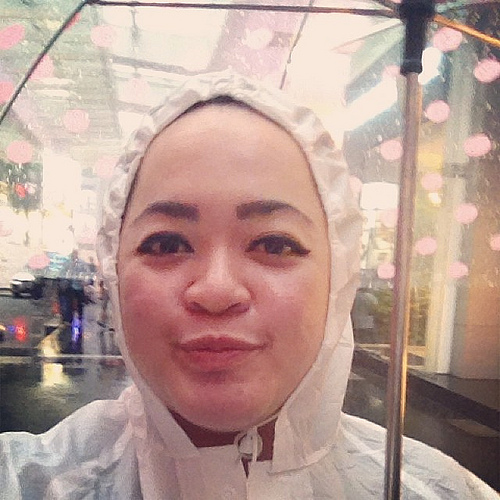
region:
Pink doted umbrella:
[359, 12, 493, 349]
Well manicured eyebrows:
[128, 185, 324, 241]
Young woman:
[58, 116, 353, 445]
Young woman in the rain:
[45, 111, 445, 445]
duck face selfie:
[142, 292, 320, 387]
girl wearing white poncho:
[25, 383, 492, 498]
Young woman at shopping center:
[75, 11, 495, 427]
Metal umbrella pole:
[377, 42, 417, 497]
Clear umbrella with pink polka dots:
[0, 0, 490, 82]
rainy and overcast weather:
[13, 13, 497, 158]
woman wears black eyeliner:
[131, 229, 312, 269]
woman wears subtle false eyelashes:
[126, 236, 315, 258]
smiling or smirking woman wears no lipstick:
[157, 324, 276, 374]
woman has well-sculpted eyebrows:
[126, 194, 318, 228]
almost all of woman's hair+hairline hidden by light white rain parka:
[111, 88, 333, 278]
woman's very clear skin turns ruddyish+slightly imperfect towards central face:
[119, 100, 334, 432]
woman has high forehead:
[121, 98, 333, 200]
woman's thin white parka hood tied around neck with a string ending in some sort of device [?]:
[231, 411, 283, 483]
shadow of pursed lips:
[166, 334, 242, 394]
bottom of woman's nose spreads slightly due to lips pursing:
[179, 275, 254, 321]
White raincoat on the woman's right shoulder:
[13, 441, 135, 496]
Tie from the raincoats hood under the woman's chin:
[226, 423, 276, 470]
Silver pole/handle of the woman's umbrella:
[393, 89, 411, 391]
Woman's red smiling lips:
[162, 331, 274, 377]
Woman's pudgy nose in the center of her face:
[177, 263, 261, 322]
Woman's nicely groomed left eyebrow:
[230, 195, 319, 231]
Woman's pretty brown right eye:
[130, 221, 210, 272]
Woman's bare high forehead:
[181, 121, 273, 199]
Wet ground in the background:
[59, 333, 112, 396]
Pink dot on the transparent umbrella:
[453, 127, 495, 172]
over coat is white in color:
[311, 348, 417, 483]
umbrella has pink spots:
[22, 37, 112, 139]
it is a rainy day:
[20, 87, 450, 456]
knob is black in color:
[392, 6, 459, 70]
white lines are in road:
[13, 345, 117, 372]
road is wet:
[15, 371, 55, 410]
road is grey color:
[15, 363, 62, 409]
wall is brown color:
[468, 303, 498, 365]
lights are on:
[327, 54, 456, 125]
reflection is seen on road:
[6, 305, 73, 397]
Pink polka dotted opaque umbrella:
[0, 0, 498, 300]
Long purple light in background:
[63, 308, 88, 351]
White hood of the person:
[86, 59, 371, 470]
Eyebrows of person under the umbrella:
[126, 198, 318, 231]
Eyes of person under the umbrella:
[132, 228, 312, 266]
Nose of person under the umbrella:
[180, 238, 253, 315]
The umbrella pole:
[375, 15, 415, 498]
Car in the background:
[2, 252, 63, 296]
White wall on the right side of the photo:
[425, 52, 497, 383]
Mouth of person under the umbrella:
[167, 333, 271, 375]